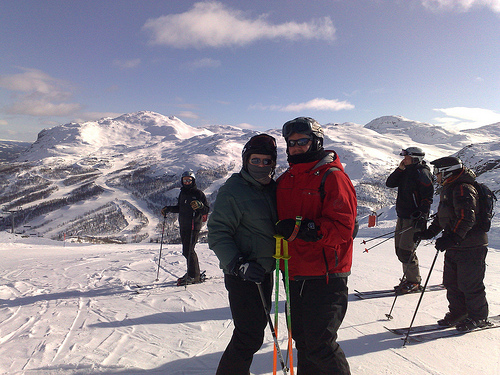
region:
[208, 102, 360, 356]
two people standing on a ski slope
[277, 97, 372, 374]
skier wearing a red ski coat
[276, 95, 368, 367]
skier wearing black ski pants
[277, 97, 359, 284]
skier wearing black sunglasses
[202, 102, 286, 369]
skier wearing a grey ski coat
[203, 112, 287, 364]
skier wearing black ski pants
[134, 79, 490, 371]
five skiers on top of a ski slope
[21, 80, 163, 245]
snow capped ski slopes in the background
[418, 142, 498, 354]
skier wearing a backpack on his back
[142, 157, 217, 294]
skier holding two ski poles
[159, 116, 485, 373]
Five skiers on top of a mountain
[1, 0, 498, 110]
Blue sky with light fluffy clouds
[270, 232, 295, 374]
Bright yellow, green, and orange ski poles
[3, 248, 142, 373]
Ski tracks in snow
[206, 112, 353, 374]
Two skiers wearing sunglasses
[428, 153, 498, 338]
Skier with back pack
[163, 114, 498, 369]
Skiers standing still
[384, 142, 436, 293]
Skier with right hand up to face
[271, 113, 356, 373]
Skier wearing red coat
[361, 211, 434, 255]
Two ski poles held in hand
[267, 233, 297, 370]
multi-colored pastel ski poles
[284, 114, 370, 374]
man in red jacket and black pants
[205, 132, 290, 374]
woman in greenish gray jacket and black pants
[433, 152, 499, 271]
man on right carries black backpack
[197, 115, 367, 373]
man and woman standing together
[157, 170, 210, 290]
person in black looking at people behind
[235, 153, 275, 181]
gray scarf covers half of face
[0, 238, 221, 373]
ski track marks in snow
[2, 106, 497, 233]
snow-covered mountains in background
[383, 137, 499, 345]
two skiers looking down the hill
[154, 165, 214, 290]
a skier on slope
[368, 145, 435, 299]
a skier on slope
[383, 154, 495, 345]
a skier on slope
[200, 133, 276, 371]
a skier on slope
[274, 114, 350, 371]
a skier on slope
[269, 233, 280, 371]
a neon colored ski pole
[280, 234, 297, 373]
a neon colored ski pole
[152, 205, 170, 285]
a black ski pole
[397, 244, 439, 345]
a black ski pole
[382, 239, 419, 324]
a black ski pole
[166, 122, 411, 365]
man and a woman posing together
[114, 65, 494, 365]
a group of people skiing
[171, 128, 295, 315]
woman with a grey jacket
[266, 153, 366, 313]
man wearing a red jacket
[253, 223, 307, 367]
multicolored ski poles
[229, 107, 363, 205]
helmets and goggles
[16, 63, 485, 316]
snowy mountainous landscape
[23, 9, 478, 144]
blue sky with white clouds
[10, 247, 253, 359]
ski tracks in the snow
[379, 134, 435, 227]
skier wearing a white helmet